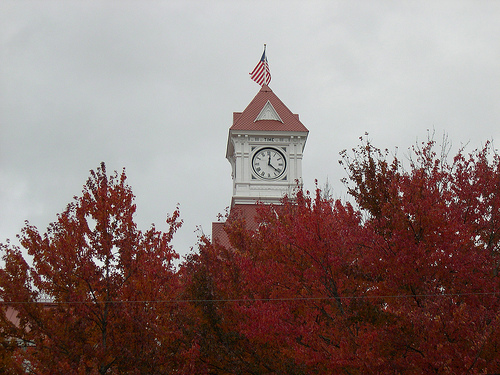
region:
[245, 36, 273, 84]
the american flag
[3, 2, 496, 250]
the sky is grey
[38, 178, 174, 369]
a colorful tree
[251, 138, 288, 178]
a white clock on a building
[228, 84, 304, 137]
the brown roof of a building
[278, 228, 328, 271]
a colorful tree branch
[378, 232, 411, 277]
a colorful tree branch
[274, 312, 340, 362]
a colorful tree branch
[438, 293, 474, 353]
a colorful tree branch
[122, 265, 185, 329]
a colorful tree branch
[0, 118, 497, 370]
pretty red trees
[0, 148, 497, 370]
dark branches on the trees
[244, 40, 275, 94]
an american flag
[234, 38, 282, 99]
flag on a roof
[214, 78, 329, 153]
brown roof on a tower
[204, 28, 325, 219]
a white tower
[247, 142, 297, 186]
a round white clock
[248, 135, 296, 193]
thin black border on a clock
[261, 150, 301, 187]
two black hands on a clock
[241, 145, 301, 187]
black roman numerals form a circle on the clock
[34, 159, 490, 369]
The trees have red leaves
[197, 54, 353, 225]
The roof of the building is red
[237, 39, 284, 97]
The flag is red, blue and white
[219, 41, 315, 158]
The flag sits on top of the tower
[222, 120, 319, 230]
The tower has a clock on the front of it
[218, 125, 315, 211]
The clock reads 12:20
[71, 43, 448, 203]
The sky is grey and hazy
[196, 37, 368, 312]
The tower is taller than the trees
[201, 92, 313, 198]
The clock is black and white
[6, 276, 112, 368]
A shorter building with a red roof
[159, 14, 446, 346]
a cloudy sky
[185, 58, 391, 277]
the roof is red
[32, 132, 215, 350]
red leaves on the tree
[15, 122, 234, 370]
the season is autumn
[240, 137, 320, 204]
a clock tower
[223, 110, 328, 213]
the clock has roman numbers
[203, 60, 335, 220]
it is 12:25 pm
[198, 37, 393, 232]
the american flag is on the tower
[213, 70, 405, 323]
the trees are red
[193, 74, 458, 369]
the clock tower is red and white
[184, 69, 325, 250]
very tall clock tower with a clock.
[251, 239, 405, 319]
trees filled with autumn leaves.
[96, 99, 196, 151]
section of cloud filled sky.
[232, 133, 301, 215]
clock on the side of a clock tower.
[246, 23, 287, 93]
flag on top of a clock tower.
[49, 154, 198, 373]
tall leafy tree.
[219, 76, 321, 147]
pointy roof on a clock tower.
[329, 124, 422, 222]
tree obscuring a cloudy sky.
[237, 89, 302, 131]
pointy roof on top of a clock tower..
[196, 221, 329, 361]
lots of red leafs.